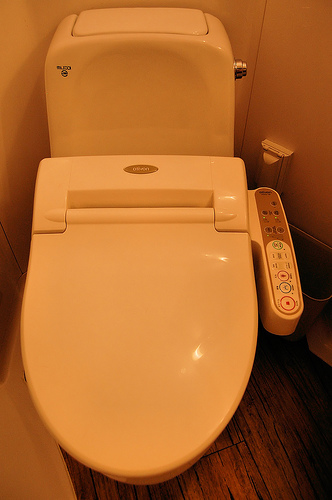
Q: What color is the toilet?
A: White.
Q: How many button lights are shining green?
A: Three.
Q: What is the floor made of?
A: Wood.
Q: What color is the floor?
A: Brown.